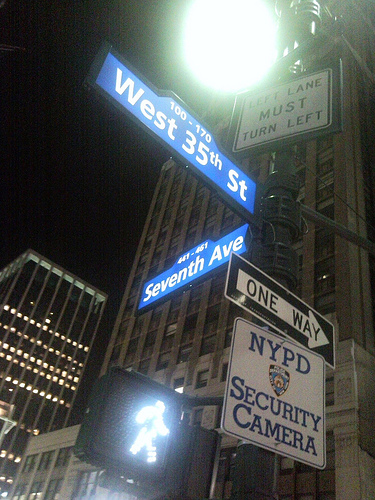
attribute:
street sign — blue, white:
[143, 217, 252, 296]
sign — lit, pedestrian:
[68, 48, 272, 235]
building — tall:
[115, 62, 368, 392]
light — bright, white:
[169, 6, 295, 99]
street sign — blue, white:
[81, 38, 260, 223]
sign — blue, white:
[220, 315, 327, 470]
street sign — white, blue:
[101, 52, 256, 216]